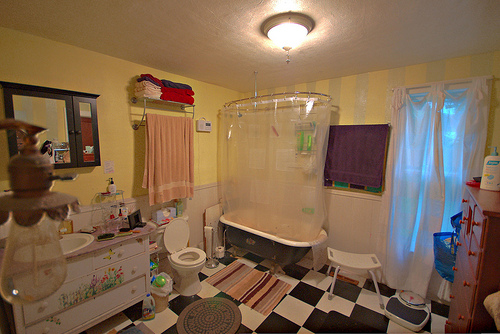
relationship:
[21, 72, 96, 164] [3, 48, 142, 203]
mirror on wall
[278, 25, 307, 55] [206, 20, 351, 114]
light on ceiling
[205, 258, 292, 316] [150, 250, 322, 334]
mat on floor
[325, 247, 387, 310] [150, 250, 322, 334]
chair on floor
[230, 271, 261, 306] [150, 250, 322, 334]
mat on floor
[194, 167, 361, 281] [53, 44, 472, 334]
tub in bathroom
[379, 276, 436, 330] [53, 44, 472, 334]
scale in bathroom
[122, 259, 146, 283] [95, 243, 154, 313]
knob on drawer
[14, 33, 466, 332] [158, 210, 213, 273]
bathroom has toilet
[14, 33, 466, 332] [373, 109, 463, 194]
bathroom has window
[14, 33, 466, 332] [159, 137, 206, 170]
bathroom has towel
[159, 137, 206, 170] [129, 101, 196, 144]
towel on rack